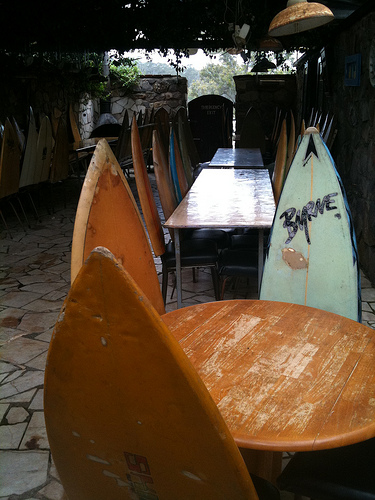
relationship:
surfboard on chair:
[127, 115, 167, 260] [143, 118, 222, 298]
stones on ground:
[0, 208, 75, 336] [0, 168, 370, 491]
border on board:
[170, 123, 184, 197] [162, 116, 196, 203]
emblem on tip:
[300, 137, 324, 168] [292, 124, 330, 143]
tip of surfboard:
[292, 124, 330, 143] [255, 121, 366, 326]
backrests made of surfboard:
[71, 135, 167, 318] [69, 139, 162, 266]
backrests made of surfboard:
[71, 135, 167, 318] [259, 126, 361, 309]